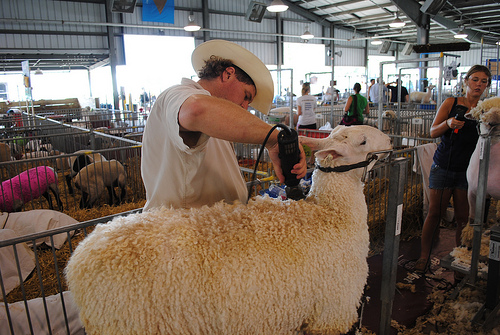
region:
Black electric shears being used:
[263, 117, 308, 206]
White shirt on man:
[116, 73, 266, 217]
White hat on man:
[182, 36, 281, 118]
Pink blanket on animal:
[0, 161, 60, 206]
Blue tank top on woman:
[431, 94, 480, 176]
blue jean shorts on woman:
[422, 157, 477, 201]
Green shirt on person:
[345, 90, 371, 123]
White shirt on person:
[292, 92, 325, 128]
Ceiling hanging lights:
[171, 3, 481, 54]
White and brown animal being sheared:
[57, 119, 398, 334]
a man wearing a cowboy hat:
[173, 25, 288, 124]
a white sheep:
[97, 114, 390, 334]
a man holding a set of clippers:
[160, 54, 329, 228]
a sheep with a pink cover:
[1, 164, 70, 204]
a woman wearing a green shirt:
[335, 75, 370, 122]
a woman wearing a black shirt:
[436, 58, 491, 152]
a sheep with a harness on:
[303, 110, 403, 190]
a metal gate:
[18, 135, 131, 212]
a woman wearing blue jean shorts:
[410, 56, 493, 210]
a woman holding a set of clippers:
[418, 49, 490, 162]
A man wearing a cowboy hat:
[138, 37, 307, 204]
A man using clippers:
[140, 39, 307, 209]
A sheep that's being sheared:
[63, 121, 393, 333]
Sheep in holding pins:
[0, 105, 135, 332]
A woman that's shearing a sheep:
[398, 64, 497, 286]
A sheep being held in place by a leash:
[61, 121, 413, 333]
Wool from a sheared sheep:
[394, 223, 491, 330]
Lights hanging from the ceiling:
[178, 1, 411, 45]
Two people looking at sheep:
[296, 79, 371, 128]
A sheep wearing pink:
[0, 164, 64, 216]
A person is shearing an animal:
[50, 21, 470, 327]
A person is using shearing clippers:
[65, 30, 416, 330]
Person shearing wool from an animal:
[40, 25, 430, 330]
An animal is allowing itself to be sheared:
[60, 30, 402, 332]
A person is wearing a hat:
[76, 30, 309, 190]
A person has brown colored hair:
[132, 32, 279, 164]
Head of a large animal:
[330, 122, 391, 162]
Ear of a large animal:
[310, 145, 340, 160]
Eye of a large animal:
[355, 130, 370, 145]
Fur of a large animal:
[128, 217, 298, 314]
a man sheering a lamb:
[66, 38, 392, 334]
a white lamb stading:
[61, 123, 399, 334]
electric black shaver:
[246, 120, 321, 199]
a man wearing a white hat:
[136, 39, 286, 209]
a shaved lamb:
[66, 153, 129, 215]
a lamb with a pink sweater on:
[0, 164, 62, 212]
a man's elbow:
[182, 98, 212, 126]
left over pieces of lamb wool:
[406, 222, 496, 333]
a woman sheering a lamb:
[424, 60, 497, 285]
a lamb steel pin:
[0, 113, 148, 230]